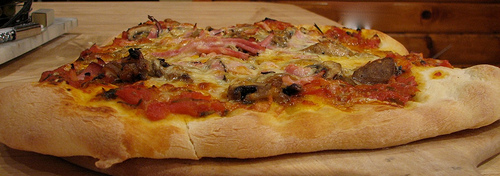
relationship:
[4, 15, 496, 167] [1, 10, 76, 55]
pizza next to item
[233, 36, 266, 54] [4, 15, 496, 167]
ham in middle of pizza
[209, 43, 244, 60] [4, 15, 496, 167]
ham in middle of pizza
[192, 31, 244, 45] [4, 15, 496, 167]
ham in middle of pizza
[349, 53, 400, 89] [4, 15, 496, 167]
mushroom on top of pizza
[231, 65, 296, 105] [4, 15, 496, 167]
mushroom on top of pizza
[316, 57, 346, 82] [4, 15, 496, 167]
mushroom on top of pizza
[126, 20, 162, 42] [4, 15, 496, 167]
mushroom on top of pizza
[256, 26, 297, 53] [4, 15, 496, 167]
mushroom on top of pizza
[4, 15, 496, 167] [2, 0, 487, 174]
pizza on pizza peel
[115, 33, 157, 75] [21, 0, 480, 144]
sausage on pizza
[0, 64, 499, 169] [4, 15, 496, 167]
crust on pizza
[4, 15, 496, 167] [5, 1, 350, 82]
pizza on table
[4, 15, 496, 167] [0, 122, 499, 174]
pizza on top of block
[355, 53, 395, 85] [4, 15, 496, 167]
meat on pizza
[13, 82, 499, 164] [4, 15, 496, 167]
crust on pizza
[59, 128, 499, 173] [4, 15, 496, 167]
peel under pizza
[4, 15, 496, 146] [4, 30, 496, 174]
pizza on block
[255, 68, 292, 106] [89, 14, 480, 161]
sausage on pizza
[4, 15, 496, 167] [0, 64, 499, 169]
pizza has crust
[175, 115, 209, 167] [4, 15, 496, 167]
crack in pizza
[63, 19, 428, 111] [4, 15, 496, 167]
cheese on pizza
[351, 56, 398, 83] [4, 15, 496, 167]
sausage on pizza